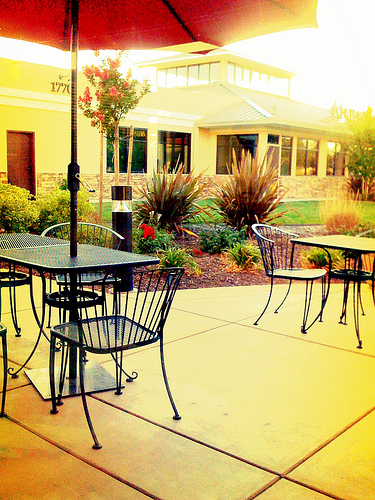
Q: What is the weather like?
A: It is clear.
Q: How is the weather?
A: It is clear.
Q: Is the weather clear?
A: Yes, it is clear.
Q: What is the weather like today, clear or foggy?
A: It is clear.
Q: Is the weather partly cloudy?
A: No, it is clear.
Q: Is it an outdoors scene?
A: Yes, it is outdoors.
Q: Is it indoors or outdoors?
A: It is outdoors.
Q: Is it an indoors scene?
A: No, it is outdoors.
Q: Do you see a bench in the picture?
A: No, there are no benches.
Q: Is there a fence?
A: No, there are no fences.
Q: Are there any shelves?
A: No, there are no shelves.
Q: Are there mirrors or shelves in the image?
A: No, there are no shelves or mirrors.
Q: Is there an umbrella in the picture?
A: Yes, there is an umbrella.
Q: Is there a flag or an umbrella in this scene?
A: Yes, there is an umbrella.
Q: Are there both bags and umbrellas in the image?
A: No, there is an umbrella but no bags.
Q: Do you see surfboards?
A: No, there are no surfboards.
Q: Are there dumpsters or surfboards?
A: No, there are no surfboards or dumpsters.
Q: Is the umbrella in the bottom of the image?
A: No, the umbrella is in the top of the image.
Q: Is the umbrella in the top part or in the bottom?
A: The umbrella is in the top of the image.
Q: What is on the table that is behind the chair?
A: The umbrella is on the table.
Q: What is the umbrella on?
A: The umbrella is on the table.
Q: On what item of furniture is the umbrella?
A: The umbrella is on the table.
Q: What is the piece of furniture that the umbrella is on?
A: The piece of furniture is a table.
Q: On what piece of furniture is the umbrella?
A: The umbrella is on the table.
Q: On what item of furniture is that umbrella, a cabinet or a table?
A: The umbrella is on a table.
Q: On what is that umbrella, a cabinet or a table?
A: The umbrella is on a table.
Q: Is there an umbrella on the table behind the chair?
A: Yes, there is an umbrella on the table.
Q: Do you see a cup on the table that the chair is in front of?
A: No, there is an umbrella on the table.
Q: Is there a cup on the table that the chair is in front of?
A: No, there is an umbrella on the table.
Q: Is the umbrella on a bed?
A: No, the umbrella is on the table.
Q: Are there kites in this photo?
A: No, there are no kites.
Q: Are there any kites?
A: No, there are no kites.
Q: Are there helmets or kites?
A: No, there are no kites or helmets.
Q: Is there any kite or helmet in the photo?
A: No, there are no kites or helmets.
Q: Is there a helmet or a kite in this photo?
A: No, there are no kites or helmets.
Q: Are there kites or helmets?
A: No, there are no kites or helmets.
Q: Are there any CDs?
A: No, there are no cds.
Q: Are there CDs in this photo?
A: No, there are no cds.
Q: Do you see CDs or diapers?
A: No, there are no CDs or diapers.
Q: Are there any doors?
A: Yes, there is a door.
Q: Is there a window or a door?
A: Yes, there is a door.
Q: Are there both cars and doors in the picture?
A: No, there is a door but no cars.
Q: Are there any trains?
A: No, there are no trains.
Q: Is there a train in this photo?
A: No, there are no trains.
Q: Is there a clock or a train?
A: No, there are no trains or clocks.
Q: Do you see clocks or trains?
A: No, there are no trains or clocks.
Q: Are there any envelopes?
A: No, there are no envelopes.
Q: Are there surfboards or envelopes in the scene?
A: No, there are no envelopes or surfboards.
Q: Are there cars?
A: No, there are no cars.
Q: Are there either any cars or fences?
A: No, there are no cars or fences.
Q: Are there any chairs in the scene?
A: Yes, there is a chair.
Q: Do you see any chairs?
A: Yes, there is a chair.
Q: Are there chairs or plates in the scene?
A: Yes, there is a chair.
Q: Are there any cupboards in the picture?
A: No, there are no cupboards.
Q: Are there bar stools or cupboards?
A: No, there are no cupboards or bar stools.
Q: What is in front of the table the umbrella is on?
A: The chair is in front of the table.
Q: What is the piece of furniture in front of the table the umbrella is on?
A: The piece of furniture is a chair.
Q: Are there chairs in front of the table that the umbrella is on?
A: Yes, there is a chair in front of the table.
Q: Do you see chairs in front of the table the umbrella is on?
A: Yes, there is a chair in front of the table.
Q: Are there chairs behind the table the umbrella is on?
A: No, the chair is in front of the table.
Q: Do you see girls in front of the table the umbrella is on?
A: No, there is a chair in front of the table.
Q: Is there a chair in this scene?
A: Yes, there is a chair.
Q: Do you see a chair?
A: Yes, there is a chair.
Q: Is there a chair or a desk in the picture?
A: Yes, there is a chair.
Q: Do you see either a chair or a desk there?
A: Yes, there is a chair.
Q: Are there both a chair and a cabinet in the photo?
A: No, there is a chair but no cabinets.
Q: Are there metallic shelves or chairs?
A: Yes, there is a metal chair.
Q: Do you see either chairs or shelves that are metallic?
A: Yes, the chair is metallic.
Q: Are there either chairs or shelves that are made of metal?
A: Yes, the chair is made of metal.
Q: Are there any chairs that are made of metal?
A: Yes, there is a chair that is made of metal.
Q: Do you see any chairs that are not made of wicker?
A: Yes, there is a chair that is made of metal.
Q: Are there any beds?
A: No, there are no beds.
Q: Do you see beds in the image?
A: No, there are no beds.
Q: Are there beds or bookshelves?
A: No, there are no beds or bookshelves.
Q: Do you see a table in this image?
A: Yes, there is a table.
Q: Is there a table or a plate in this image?
A: Yes, there is a table.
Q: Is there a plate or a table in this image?
A: Yes, there is a table.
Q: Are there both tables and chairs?
A: Yes, there are both a table and a chair.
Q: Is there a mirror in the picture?
A: No, there are no mirrors.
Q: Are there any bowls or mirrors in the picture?
A: No, there are no mirrors or bowls.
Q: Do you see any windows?
A: Yes, there are windows.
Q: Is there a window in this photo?
A: Yes, there are windows.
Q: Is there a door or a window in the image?
A: Yes, there are windows.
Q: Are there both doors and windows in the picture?
A: Yes, there are both windows and a door.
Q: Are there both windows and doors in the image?
A: Yes, there are both windows and a door.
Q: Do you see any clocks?
A: No, there are no clocks.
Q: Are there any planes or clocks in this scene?
A: No, there are no clocks or planes.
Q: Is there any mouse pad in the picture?
A: No, there are no mouse pads.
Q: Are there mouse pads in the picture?
A: No, there are no mouse pads.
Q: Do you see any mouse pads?
A: No, there are no mouse pads.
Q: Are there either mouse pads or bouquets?
A: No, there are no mouse pads or bouquets.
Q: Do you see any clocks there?
A: No, there are no clocks.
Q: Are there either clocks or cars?
A: No, there are no clocks or cars.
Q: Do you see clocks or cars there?
A: No, there are no clocks or cars.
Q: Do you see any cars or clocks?
A: No, there are no clocks or cars.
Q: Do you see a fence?
A: No, there are no fences.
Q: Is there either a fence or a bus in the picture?
A: No, there are no fences or buses.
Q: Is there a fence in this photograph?
A: No, there are no fences.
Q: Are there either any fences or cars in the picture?
A: No, there are no fences or cars.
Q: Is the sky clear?
A: Yes, the sky is clear.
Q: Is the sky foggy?
A: No, the sky is clear.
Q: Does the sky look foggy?
A: No, the sky is clear.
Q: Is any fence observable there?
A: No, there are no fences.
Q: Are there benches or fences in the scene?
A: No, there are no fences or benches.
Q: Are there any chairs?
A: Yes, there is a chair.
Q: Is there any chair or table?
A: Yes, there is a chair.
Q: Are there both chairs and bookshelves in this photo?
A: No, there is a chair but no bookshelves.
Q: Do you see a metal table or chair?
A: Yes, there is a metal chair.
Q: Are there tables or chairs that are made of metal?
A: Yes, the chair is made of metal.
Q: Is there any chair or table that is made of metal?
A: Yes, the chair is made of metal.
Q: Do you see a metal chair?
A: Yes, there is a metal chair.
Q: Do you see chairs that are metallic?
A: Yes, there is a metal chair.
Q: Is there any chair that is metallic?
A: Yes, there is a chair that is metallic.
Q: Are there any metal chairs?
A: Yes, there is a chair that is made of metal.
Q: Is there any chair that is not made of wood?
A: Yes, there is a chair that is made of metal.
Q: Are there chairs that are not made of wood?
A: Yes, there is a chair that is made of metal.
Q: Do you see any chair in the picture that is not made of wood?
A: Yes, there is a chair that is made of metal.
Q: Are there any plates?
A: No, there are no plates.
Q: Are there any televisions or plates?
A: No, there are no plates or televisions.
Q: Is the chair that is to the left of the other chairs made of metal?
A: Yes, the chair is made of metal.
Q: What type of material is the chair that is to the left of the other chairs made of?
A: The chair is made of metal.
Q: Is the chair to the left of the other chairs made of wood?
A: No, the chair is made of metal.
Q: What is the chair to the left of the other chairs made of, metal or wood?
A: The chair is made of metal.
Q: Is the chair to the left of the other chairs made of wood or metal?
A: The chair is made of metal.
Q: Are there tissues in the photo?
A: No, there are no tissues.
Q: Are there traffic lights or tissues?
A: No, there are no tissues or traffic lights.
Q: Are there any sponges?
A: No, there are no sponges.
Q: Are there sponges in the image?
A: No, there are no sponges.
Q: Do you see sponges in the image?
A: No, there are no sponges.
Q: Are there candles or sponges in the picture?
A: No, there are no sponges or candles.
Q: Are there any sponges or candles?
A: No, there are no sponges or candles.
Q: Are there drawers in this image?
A: No, there are no drawers.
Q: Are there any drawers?
A: No, there are no drawers.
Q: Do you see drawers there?
A: No, there are no drawers.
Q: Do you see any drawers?
A: No, there are no drawers.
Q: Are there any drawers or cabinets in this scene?
A: No, there are no drawers or cabinets.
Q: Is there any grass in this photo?
A: Yes, there is grass.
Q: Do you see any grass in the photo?
A: Yes, there is grass.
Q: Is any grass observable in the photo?
A: Yes, there is grass.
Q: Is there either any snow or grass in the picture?
A: Yes, there is grass.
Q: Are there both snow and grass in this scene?
A: No, there is grass but no snow.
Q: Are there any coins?
A: No, there are no coins.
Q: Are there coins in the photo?
A: No, there are no coins.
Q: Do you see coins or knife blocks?
A: No, there are no coins or knife blocks.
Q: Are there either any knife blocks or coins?
A: No, there are no coins or knife blocks.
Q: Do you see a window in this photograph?
A: Yes, there is a window.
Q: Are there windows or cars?
A: Yes, there is a window.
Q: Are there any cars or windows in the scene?
A: Yes, there is a window.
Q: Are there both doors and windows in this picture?
A: Yes, there are both a window and a door.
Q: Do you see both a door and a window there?
A: Yes, there are both a window and a door.